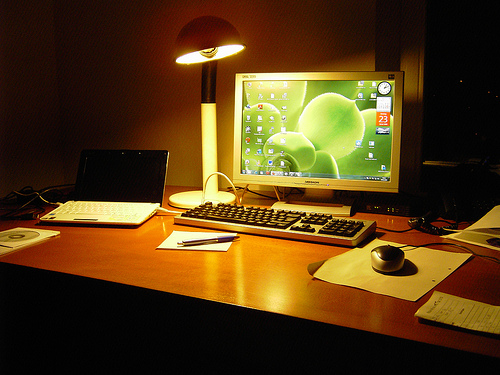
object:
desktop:
[233, 67, 405, 216]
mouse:
[373, 245, 406, 274]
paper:
[308, 234, 472, 300]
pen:
[179, 234, 240, 247]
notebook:
[152, 230, 240, 256]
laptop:
[47, 150, 174, 226]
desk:
[3, 190, 499, 348]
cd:
[3, 227, 47, 244]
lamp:
[181, 22, 234, 205]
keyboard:
[190, 202, 378, 241]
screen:
[82, 154, 160, 196]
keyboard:
[52, 203, 149, 229]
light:
[181, 47, 241, 64]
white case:
[6, 227, 63, 255]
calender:
[376, 95, 395, 133]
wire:
[199, 169, 251, 213]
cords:
[10, 186, 58, 216]